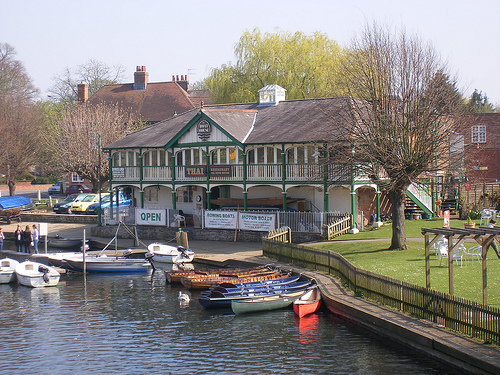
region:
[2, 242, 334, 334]
eleven boats tied to wall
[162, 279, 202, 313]
a bird swims in water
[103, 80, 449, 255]
a green and white building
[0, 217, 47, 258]
four people standing near water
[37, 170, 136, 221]
five cars are parked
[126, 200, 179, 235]
a white sign with green letters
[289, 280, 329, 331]
one red boat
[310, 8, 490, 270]
a tree without leaves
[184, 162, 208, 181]
a brown sign with yellow letters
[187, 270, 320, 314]
two boats are blue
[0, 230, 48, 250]
a group of people near the water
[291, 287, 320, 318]
a small red canoe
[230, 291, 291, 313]
a light green canoe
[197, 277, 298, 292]
a row of blue boats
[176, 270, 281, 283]
two brown boats side by side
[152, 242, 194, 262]
a white motorboat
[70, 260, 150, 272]
a silver and blue motorboat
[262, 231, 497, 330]
a fence next to the water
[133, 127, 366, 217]
a large white and green building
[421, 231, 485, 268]
white chairs on a lawn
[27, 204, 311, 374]
small boats in the water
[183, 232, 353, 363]
kayaks on the water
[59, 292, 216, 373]
a body of water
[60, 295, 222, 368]
a body of calm water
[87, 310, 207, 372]
a body of water that is calm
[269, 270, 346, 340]
a red kyak in the water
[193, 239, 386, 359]
kyaks tied up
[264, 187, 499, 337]
a short wooden fence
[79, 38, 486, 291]
a house with a balcony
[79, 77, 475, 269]
a white house with green trim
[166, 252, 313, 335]
several boats in the water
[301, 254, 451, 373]
A sidewalk along the water's edge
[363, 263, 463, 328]
a wooden fence seperating the sidewalk and the grass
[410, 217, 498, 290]
a wooden gazebo in the park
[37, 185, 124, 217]
cars parked in the parking lot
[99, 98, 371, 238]
a white building with green trim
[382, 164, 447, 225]
steps leading up to the second floor of the building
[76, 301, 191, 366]
the water is rippled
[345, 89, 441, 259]
a leafless tree in the park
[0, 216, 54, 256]
people standing by the water's edge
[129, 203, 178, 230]
white and green sign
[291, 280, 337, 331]
red and white canoe in water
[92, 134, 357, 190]
balcony on front of building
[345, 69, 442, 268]
tree with no leaves on grass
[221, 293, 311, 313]
green and white canoe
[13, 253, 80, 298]
white motor boat in water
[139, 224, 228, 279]
boat tied to dock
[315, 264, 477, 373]
walkway along the water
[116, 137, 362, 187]
green trim on white building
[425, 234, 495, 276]
white chairs on grass